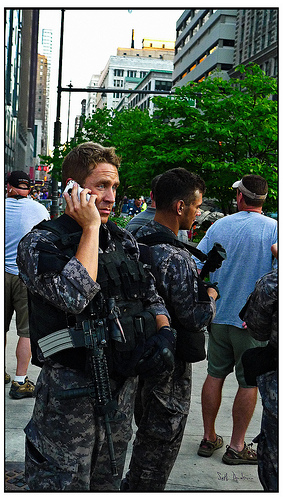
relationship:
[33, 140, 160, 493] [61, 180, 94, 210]
man on cellphone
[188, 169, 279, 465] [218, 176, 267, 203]
man wearing visor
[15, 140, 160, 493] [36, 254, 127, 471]
man with guns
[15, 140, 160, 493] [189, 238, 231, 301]
man with guns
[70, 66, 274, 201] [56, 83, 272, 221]
leaves on trees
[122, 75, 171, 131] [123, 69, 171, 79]
building with roof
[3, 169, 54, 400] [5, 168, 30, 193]
man wearing baseball hat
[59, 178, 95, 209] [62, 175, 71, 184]
cell phone on ear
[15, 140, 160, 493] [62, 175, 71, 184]
man has ear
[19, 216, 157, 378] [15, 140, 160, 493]
vest on man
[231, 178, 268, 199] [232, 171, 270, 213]
visor on head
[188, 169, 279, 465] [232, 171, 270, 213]
man has head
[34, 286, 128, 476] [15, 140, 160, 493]
gun belongs to man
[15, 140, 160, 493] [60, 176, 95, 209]
man talking on phone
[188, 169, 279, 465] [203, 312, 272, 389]
man wearing shorts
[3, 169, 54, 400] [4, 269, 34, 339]
man wearing shorts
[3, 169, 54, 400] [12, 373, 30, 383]
man wearing sock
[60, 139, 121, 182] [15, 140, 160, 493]
hair on man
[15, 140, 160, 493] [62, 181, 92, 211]
man talking on cellphone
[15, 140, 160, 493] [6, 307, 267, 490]
man standing on street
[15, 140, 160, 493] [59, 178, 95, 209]
man talking on cell phone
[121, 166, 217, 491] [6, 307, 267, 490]
soldier standing on street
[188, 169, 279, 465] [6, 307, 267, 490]
man standing on street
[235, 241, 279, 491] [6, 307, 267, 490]
soldier standing on street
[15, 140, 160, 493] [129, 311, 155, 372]
man carrying gun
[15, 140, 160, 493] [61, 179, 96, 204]
man on phone